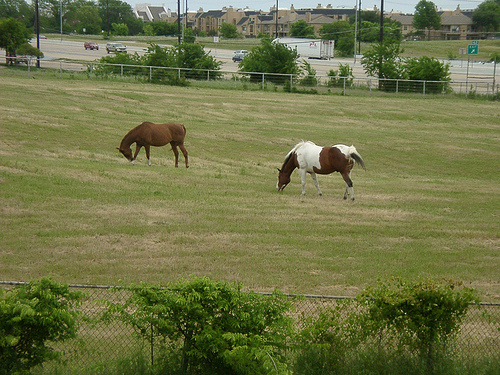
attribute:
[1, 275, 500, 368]
fences — chain link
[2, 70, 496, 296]
grass — short, pasture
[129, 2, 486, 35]
houses — apartments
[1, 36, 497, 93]
street — nearby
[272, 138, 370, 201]
horse with white — grazing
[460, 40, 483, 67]
sign — green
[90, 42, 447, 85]
bushes — smaller, green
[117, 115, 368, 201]
two horses — grazing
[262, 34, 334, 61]
truck — white